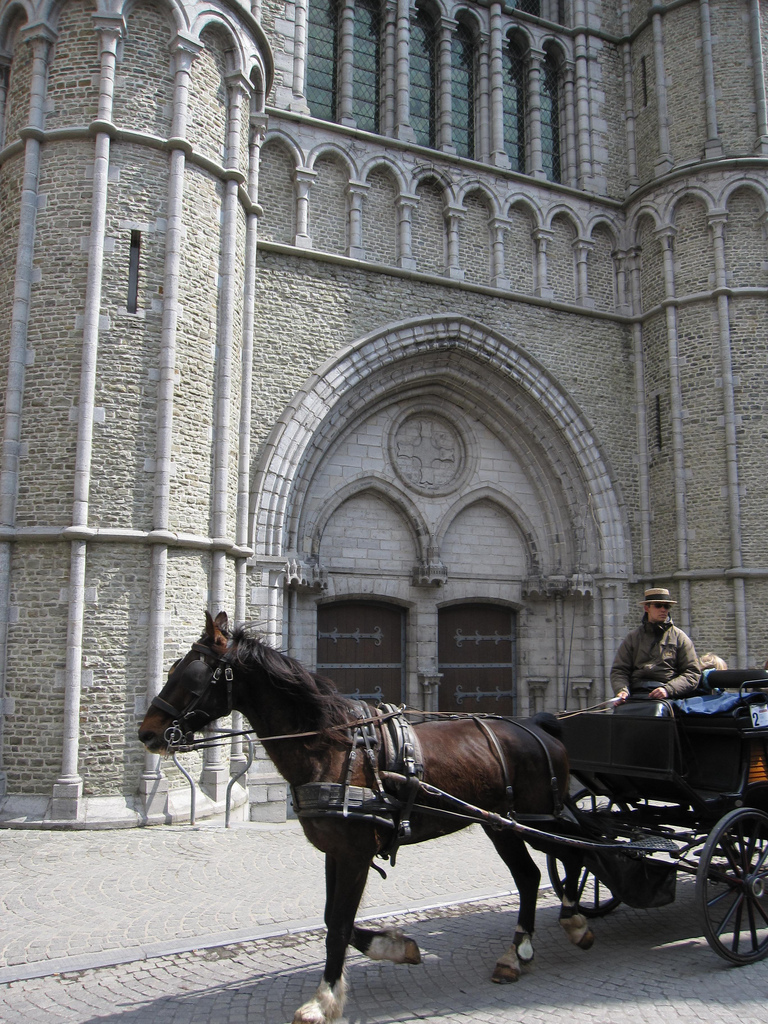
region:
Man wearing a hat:
[628, 583, 680, 611]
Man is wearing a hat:
[628, 581, 683, 610]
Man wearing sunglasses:
[642, 597, 674, 611]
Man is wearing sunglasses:
[644, 595, 681, 613]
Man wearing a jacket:
[604, 615, 707, 703]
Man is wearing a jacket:
[601, 613, 709, 707]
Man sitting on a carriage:
[537, 570, 766, 981]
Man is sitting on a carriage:
[528, 571, 764, 976]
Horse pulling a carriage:
[102, 565, 766, 1022]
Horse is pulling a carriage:
[129, 581, 766, 1019]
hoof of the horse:
[386, 939, 422, 959]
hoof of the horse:
[503, 954, 533, 975]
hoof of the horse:
[556, 922, 588, 949]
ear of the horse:
[199, 626, 219, 639]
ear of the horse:
[216, 614, 239, 628]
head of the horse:
[131, 633, 253, 747]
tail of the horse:
[552, 716, 587, 799]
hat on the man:
[640, 586, 679, 604]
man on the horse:
[615, 580, 703, 702]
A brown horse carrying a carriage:
[137, 608, 594, 1022]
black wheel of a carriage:
[697, 803, 766, 964]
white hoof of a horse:
[292, 978, 349, 1022]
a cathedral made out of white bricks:
[0, 0, 765, 825]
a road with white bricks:
[2, 850, 766, 1022]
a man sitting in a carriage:
[608, 587, 699, 706]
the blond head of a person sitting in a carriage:
[698, 650, 725, 673]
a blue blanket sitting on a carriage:
[673, 689, 756, 713]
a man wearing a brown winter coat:
[610, 625, 701, 701]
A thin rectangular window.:
[123, 229, 142, 314]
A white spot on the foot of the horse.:
[514, 936, 533, 963]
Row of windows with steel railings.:
[307, 0, 563, 183]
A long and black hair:
[231, 619, 346, 747]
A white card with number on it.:
[743, 702, 766, 731]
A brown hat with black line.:
[635, 586, 681, 604]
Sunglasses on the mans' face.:
[644, 601, 672, 622]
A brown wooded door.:
[314, 593, 403, 706]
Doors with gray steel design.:
[312, 599, 519, 713]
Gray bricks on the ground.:
[0, 826, 231, 929]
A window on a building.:
[543, 38, 575, 180]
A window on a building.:
[497, 25, 528, 167]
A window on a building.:
[445, 7, 480, 161]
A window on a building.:
[409, 4, 436, 148]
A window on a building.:
[350, 5, 381, 126]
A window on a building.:
[306, 7, 343, 130]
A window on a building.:
[506, 5, 541, 20]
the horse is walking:
[136, 611, 594, 1021]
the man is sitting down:
[611, 588, 703, 717]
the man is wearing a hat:
[610, 587, 701, 718]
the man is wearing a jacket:
[613, 587, 701, 717]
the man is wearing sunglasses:
[609, 584, 702, 721]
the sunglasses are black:
[642, 601, 670, 609]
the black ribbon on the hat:
[640, 588, 678, 606]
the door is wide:
[315, 602, 408, 711]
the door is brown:
[442, 603, 515, 714]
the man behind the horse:
[139, 588, 766, 1019]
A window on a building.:
[535, 37, 582, 176]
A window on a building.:
[495, 23, 535, 173]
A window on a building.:
[450, 7, 480, 158]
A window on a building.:
[404, 7, 438, 146]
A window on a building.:
[352, 7, 386, 130]